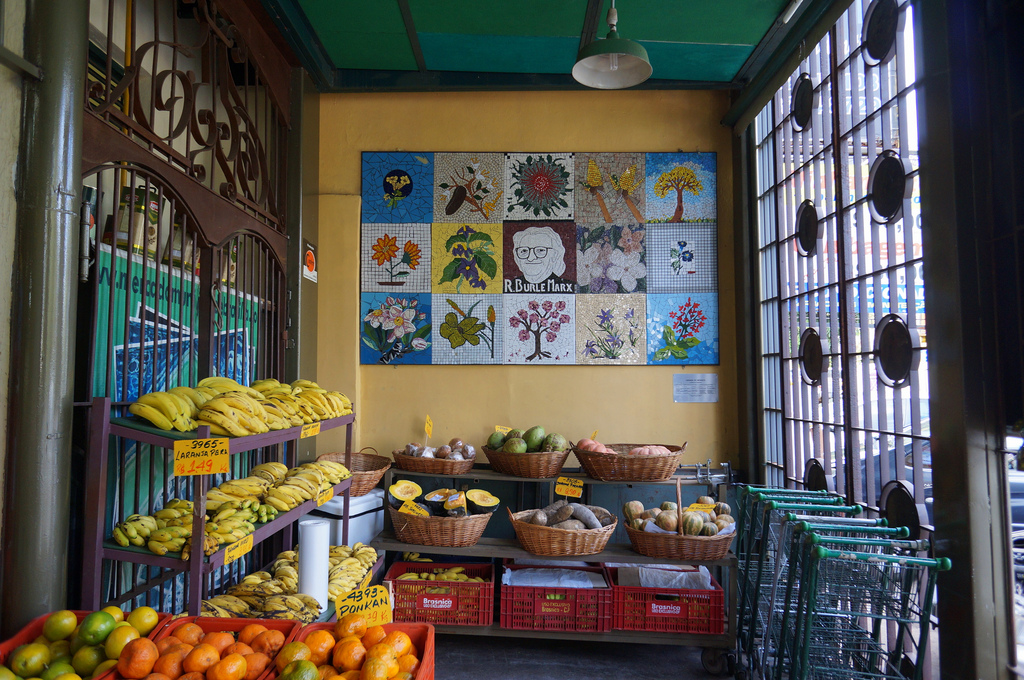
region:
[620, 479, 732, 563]
fruit in a basket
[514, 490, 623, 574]
fruit in a basket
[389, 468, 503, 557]
fruit in a basket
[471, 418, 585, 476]
fruit in a basket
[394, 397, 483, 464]
fruit in a basket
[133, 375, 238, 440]
bananas on a shelf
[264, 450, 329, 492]
bananas on a shelf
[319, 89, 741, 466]
artwork hanging on yellow wall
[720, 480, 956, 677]
green and silver shopping carts are lined up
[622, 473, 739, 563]
squash in a brown wicker basket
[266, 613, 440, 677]
orange fruit in a red basket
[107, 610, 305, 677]
orange fruit in a red basket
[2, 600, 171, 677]
green and yellow fruit in a red basket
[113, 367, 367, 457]
yellow bananas stacked on top shelf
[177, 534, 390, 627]
yellow bananas on bottom shelf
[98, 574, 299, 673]
a view of fruits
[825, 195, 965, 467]
a view of gate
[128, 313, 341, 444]
a view of fruits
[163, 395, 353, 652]
a group of fruits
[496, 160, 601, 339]
design in th e wall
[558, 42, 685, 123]
a view of light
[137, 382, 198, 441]
bunch of bananas sitting on shelf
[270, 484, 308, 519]
bunch of bananas sitting on shelf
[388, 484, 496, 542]
basket of squash sitting on shelf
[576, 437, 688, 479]
basket of pumpkins sitting on shelf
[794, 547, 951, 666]
green shopping cart sitting near window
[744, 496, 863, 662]
green shopping cart sitting near window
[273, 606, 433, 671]
red crate full of oranges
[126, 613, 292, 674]
red crate full of oranges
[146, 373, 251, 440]
yellow and green bananas on shelf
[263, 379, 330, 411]
yellow and green bananas on shelf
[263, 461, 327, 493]
yellow and green bananas on shelf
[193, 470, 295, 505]
yellow and green bananas on shelf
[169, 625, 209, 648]
orange oranges in red box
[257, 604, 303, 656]
orange oranges in red box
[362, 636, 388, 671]
orange oranges in red box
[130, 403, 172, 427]
A banana on a shelf.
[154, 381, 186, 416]
A banana on a shelf.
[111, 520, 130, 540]
A banana on a shelf.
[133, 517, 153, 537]
A banana on a shelf.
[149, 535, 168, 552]
A banana on a shelf.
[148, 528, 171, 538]
A banana on a shelf.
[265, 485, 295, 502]
A banana on a shelf.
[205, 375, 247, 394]
A banana on a shelf.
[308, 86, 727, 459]
decorative panels on a yellow wall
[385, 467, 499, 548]
cut acorn squash in a basket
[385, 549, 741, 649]
three red plastic crates on a shelf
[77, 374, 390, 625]
open purple rack with bananas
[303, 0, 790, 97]
green metal lamp hanging from green and blue ceiling